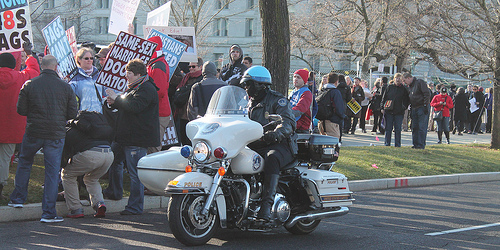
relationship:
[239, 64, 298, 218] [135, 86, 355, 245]
policeman on motorcycle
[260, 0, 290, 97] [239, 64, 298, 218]
tree behind policeman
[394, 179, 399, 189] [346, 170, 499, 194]
line on curb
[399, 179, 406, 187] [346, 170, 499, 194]
line on curb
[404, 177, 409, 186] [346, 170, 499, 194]
line on curb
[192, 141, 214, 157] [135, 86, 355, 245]
headlight on motorcycle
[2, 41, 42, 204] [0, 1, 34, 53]
person holding sign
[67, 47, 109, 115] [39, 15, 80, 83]
person holding sign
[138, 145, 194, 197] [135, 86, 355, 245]
sidecar on motorcycle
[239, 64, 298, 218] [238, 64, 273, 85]
policeman wearing helmet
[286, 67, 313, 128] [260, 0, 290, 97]
person near tree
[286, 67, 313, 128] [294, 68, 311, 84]
person wearing hat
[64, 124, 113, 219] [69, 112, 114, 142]
man wearing backpack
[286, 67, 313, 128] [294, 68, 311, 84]
person in hat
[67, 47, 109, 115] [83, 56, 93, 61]
person wearing sunglasses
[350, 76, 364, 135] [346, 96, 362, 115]
man holding sign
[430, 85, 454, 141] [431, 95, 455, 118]
woman wearing coat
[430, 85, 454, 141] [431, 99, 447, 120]
woman carrying purse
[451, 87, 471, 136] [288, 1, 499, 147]
person under tree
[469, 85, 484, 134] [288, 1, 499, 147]
person under tree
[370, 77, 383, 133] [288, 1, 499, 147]
person under tree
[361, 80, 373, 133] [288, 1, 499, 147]
person under tree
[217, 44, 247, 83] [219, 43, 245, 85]
man wearing hoodie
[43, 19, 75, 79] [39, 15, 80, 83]
writing on sign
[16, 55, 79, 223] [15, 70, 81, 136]
person wearing coat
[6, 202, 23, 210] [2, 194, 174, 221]
foot on curb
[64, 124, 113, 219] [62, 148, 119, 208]
man wearing pants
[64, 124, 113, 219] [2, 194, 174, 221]
man near curb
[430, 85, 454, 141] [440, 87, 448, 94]
woman wearing hat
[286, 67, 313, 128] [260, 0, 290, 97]
person by tree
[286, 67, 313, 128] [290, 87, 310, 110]
person wearing scarf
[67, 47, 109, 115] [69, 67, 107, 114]
person wearing jacket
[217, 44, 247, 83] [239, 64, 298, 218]
man behind policeman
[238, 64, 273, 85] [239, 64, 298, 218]
helmet on policeman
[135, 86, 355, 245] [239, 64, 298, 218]
motorcycle under policeman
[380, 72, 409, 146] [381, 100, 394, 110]
person carrying bag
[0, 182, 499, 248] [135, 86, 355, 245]
road under motorcycle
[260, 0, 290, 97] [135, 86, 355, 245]
tree behind motorcycle